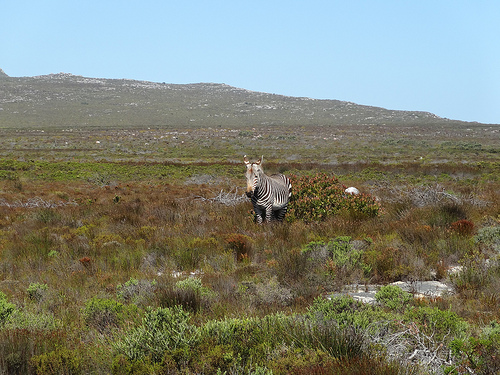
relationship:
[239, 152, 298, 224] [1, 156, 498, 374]
zebra in a field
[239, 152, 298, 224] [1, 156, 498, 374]
zebra in field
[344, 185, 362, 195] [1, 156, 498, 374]
object in field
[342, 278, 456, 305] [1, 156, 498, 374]
rock in field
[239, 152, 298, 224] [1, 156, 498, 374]
zebra standing in field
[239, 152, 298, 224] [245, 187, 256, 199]
zebra has a nose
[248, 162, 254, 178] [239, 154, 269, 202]
mark on top of zebra's head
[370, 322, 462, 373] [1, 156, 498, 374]
sticks in field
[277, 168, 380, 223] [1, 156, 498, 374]
bush in field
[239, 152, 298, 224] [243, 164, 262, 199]
zebra has a face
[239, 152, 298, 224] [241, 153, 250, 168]
zebra has an ear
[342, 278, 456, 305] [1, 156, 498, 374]
rock on field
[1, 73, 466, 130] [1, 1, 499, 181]
mountain in distance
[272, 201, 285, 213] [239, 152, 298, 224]
underbelly of zebra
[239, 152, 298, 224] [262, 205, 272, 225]
zebra has a leg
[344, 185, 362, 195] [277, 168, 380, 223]
object peeking over a bush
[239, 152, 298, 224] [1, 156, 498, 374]
zebra standing on field